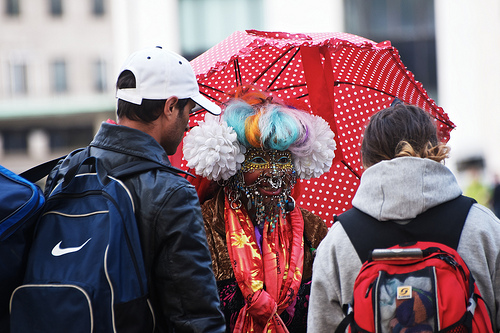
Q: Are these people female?
A: No, they are both male and female.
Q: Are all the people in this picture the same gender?
A: No, they are both male and female.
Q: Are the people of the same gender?
A: No, they are both male and female.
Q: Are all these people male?
A: No, they are both male and female.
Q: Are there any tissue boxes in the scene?
A: No, there are no tissue boxes.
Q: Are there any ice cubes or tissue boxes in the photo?
A: No, there are no tissue boxes or ice cubes.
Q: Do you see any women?
A: Yes, there is a woman.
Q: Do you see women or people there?
A: Yes, there is a woman.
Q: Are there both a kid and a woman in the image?
A: No, there is a woman but no children.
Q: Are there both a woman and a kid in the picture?
A: No, there is a woman but no children.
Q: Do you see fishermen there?
A: No, there are no fishermen.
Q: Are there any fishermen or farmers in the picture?
A: No, there are no fishermen or farmers.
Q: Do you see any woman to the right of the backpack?
A: Yes, there is a woman to the right of the backpack.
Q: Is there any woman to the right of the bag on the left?
A: Yes, there is a woman to the right of the backpack.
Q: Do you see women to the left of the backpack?
A: No, the woman is to the right of the backpack.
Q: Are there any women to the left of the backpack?
A: No, the woman is to the right of the backpack.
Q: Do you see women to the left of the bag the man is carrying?
A: No, the woman is to the right of the backpack.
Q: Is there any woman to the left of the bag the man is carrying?
A: No, the woman is to the right of the backpack.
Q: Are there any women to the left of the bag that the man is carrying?
A: No, the woman is to the right of the backpack.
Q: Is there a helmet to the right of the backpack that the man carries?
A: No, there is a woman to the right of the backpack.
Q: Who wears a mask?
A: The woman wears a mask.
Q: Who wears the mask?
A: The woman wears a mask.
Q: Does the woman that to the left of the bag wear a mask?
A: Yes, the woman wears a mask.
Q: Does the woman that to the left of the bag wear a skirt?
A: No, the woman wears a mask.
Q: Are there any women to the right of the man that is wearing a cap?
A: Yes, there is a woman to the right of the man.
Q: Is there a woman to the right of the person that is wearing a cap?
A: Yes, there is a woman to the right of the man.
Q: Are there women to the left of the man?
A: No, the woman is to the right of the man.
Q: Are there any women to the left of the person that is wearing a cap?
A: No, the woman is to the right of the man.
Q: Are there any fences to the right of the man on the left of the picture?
A: No, there is a woman to the right of the man.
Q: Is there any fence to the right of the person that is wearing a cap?
A: No, there is a woman to the right of the man.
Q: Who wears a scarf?
A: The woman wears a scarf.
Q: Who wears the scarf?
A: The woman wears a scarf.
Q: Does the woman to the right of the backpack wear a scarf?
A: Yes, the woman wears a scarf.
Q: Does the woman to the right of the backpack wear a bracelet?
A: No, the woman wears a scarf.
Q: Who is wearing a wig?
A: The woman is wearing a wig.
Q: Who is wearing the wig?
A: The woman is wearing a wig.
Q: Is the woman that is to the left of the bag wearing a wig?
A: Yes, the woman is wearing a wig.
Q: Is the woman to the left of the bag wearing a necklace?
A: No, the woman is wearing a wig.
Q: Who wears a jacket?
A: The woman wears a jacket.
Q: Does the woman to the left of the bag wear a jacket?
A: Yes, the woman wears a jacket.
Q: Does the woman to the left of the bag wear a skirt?
A: No, the woman wears a jacket.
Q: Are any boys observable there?
A: No, there are no boys.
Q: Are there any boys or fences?
A: No, there are no boys or fences.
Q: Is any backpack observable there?
A: Yes, there is a backpack.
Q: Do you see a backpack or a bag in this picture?
A: Yes, there is a backpack.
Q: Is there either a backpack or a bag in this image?
A: Yes, there is a backpack.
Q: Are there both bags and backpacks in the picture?
A: Yes, there are both a backpack and a bag.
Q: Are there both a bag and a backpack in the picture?
A: Yes, there are both a backpack and a bag.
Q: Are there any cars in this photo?
A: No, there are no cars.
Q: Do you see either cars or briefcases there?
A: No, there are no cars or briefcases.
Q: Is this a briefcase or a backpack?
A: This is a backpack.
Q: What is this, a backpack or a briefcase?
A: This is a backpack.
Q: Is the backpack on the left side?
A: Yes, the backpack is on the left of the image.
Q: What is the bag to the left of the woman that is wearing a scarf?
A: The bag is a backpack.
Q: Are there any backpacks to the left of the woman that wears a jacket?
A: Yes, there is a backpack to the left of the woman.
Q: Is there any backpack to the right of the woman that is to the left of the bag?
A: No, the backpack is to the left of the woman.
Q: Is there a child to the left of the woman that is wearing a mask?
A: No, there is a backpack to the left of the woman.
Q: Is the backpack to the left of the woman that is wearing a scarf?
A: Yes, the backpack is to the left of the woman.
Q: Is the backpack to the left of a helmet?
A: No, the backpack is to the left of the woman.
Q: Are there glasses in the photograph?
A: No, there are no glasses.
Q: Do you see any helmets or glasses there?
A: No, there are no glasses or helmets.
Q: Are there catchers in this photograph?
A: No, there are no catchers.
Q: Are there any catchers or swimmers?
A: No, there are no catchers or swimmers.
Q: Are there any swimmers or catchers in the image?
A: No, there are no catchers or swimmers.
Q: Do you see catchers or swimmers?
A: No, there are no catchers or swimmers.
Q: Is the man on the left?
A: Yes, the man is on the left of the image.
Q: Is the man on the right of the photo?
A: No, the man is on the left of the image.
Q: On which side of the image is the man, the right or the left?
A: The man is on the left of the image.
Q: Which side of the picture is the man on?
A: The man is on the left of the image.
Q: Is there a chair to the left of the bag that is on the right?
A: No, there is a man to the left of the bag.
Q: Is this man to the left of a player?
A: No, the man is to the left of the bag.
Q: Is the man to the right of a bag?
A: No, the man is to the left of a bag.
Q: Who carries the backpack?
A: The man carries the backpack.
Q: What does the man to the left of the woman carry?
A: The man carries a backpack.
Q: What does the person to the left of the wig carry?
A: The man carries a backpack.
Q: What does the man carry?
A: The man carries a backpack.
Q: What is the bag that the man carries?
A: The bag is a backpack.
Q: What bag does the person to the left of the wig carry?
A: The man carries a backpack.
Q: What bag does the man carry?
A: The man carries a backpack.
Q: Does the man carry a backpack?
A: Yes, the man carries a backpack.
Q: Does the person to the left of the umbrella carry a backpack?
A: Yes, the man carries a backpack.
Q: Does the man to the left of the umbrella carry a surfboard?
A: No, the man carries a backpack.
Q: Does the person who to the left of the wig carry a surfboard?
A: No, the man carries a backpack.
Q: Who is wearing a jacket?
A: The man is wearing a jacket.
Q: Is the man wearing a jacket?
A: Yes, the man is wearing a jacket.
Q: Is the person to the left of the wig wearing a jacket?
A: Yes, the man is wearing a jacket.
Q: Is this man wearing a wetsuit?
A: No, the man is wearing a jacket.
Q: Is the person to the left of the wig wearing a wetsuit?
A: No, the man is wearing a jacket.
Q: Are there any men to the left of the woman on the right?
A: Yes, there is a man to the left of the woman.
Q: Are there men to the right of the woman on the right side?
A: No, the man is to the left of the woman.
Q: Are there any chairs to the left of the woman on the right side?
A: No, there is a man to the left of the woman.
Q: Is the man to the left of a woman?
A: Yes, the man is to the left of a woman.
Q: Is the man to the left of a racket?
A: No, the man is to the left of a woman.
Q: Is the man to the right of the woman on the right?
A: No, the man is to the left of the woman.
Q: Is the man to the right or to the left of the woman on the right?
A: The man is to the left of the woman.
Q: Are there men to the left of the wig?
A: Yes, there is a man to the left of the wig.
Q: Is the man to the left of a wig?
A: Yes, the man is to the left of a wig.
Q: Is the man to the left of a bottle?
A: No, the man is to the left of a wig.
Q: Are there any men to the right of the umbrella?
A: No, the man is to the left of the umbrella.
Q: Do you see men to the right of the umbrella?
A: No, the man is to the left of the umbrella.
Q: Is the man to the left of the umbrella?
A: Yes, the man is to the left of the umbrella.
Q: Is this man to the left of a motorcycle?
A: No, the man is to the left of the umbrella.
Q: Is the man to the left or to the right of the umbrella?
A: The man is to the left of the umbrella.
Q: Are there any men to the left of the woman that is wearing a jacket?
A: Yes, there is a man to the left of the woman.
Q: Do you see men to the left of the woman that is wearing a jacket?
A: Yes, there is a man to the left of the woman.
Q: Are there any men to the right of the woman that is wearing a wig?
A: No, the man is to the left of the woman.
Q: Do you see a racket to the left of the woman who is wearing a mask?
A: No, there is a man to the left of the woman.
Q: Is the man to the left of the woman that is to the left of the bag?
A: Yes, the man is to the left of the woman.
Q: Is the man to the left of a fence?
A: No, the man is to the left of the woman.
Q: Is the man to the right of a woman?
A: No, the man is to the left of a woman.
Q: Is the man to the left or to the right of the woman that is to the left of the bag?
A: The man is to the left of the woman.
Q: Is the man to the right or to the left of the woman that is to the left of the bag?
A: The man is to the left of the woman.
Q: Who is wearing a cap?
A: The man is wearing a cap.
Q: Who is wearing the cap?
A: The man is wearing a cap.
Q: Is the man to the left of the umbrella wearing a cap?
A: Yes, the man is wearing a cap.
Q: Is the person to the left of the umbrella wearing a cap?
A: Yes, the man is wearing a cap.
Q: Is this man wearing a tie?
A: No, the man is wearing a cap.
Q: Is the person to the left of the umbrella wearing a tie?
A: No, the man is wearing a cap.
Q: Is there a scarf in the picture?
A: Yes, there is a scarf.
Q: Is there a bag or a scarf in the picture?
A: Yes, there is a scarf.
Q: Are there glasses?
A: No, there are no glasses.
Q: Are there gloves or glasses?
A: No, there are no glasses or gloves.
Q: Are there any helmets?
A: No, there are no helmets.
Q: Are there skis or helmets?
A: No, there are no helmets or skis.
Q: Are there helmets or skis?
A: No, there are no helmets or skis.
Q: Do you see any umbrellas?
A: Yes, there is an umbrella.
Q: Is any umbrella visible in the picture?
A: Yes, there is an umbrella.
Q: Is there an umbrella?
A: Yes, there is an umbrella.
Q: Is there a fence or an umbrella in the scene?
A: Yes, there is an umbrella.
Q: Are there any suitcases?
A: No, there are no suitcases.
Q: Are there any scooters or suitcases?
A: No, there are no suitcases or scooters.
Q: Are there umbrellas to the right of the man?
A: Yes, there is an umbrella to the right of the man.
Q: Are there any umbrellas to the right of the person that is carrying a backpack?
A: Yes, there is an umbrella to the right of the man.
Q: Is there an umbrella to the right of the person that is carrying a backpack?
A: Yes, there is an umbrella to the right of the man.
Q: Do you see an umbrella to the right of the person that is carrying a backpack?
A: Yes, there is an umbrella to the right of the man.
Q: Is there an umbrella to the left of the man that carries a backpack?
A: No, the umbrella is to the right of the man.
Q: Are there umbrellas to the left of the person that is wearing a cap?
A: No, the umbrella is to the right of the man.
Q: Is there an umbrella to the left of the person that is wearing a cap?
A: No, the umbrella is to the right of the man.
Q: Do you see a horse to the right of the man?
A: No, there is an umbrella to the right of the man.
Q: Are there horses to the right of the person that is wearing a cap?
A: No, there is an umbrella to the right of the man.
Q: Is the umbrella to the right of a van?
A: No, the umbrella is to the right of the man.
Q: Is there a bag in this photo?
A: Yes, there is a bag.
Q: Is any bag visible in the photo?
A: Yes, there is a bag.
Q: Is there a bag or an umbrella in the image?
A: Yes, there is a bag.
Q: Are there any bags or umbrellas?
A: Yes, there is a bag.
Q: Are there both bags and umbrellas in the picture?
A: Yes, there are both a bag and an umbrella.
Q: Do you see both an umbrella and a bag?
A: Yes, there are both a bag and an umbrella.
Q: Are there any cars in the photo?
A: No, there are no cars.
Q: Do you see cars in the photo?
A: No, there are no cars.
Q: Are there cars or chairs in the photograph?
A: No, there are no cars or chairs.